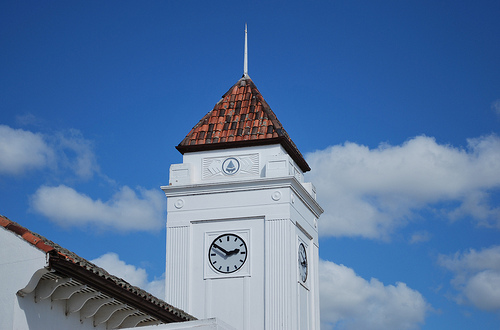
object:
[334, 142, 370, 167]
part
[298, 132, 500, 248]
cloud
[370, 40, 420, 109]
part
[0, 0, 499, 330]
sky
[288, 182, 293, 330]
edge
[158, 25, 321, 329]
tower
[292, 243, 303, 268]
part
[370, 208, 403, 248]
edge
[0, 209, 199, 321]
edge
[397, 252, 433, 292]
part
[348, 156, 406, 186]
part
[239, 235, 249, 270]
edge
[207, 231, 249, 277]
clock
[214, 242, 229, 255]
hands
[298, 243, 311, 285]
clock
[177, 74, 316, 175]
roof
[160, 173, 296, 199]
trim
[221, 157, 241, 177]
logo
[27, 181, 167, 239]
cloud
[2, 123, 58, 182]
cloud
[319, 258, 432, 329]
cloud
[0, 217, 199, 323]
roof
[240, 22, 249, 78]
antenna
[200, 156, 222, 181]
design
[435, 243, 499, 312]
clouds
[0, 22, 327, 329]
building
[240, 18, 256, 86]
top